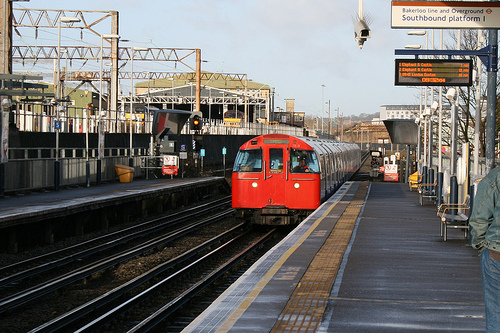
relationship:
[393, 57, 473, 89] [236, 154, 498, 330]
sign at a rail station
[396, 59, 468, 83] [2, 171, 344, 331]
sign at a railway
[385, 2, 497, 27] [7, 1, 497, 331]
sign at a train station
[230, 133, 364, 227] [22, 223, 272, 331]
red train on tracks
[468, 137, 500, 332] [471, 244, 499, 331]
man wears jeans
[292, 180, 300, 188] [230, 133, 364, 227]
headlight on red train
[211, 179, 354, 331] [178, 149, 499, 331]
line on platform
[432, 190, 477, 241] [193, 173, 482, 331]
bench on platform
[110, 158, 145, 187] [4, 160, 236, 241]
bucket on platform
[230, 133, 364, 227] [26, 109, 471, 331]
red train parked at station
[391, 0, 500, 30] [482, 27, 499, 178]
sign hangs from pole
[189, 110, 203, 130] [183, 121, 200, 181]
light on pole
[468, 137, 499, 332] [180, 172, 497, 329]
man on platform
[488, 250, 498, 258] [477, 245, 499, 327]
brown tag on jeans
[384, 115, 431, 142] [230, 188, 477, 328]
panel on platform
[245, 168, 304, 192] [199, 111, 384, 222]
light on train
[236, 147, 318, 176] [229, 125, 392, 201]
windshield on train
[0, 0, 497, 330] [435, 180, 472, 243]
station has seating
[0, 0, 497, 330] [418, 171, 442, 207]
station has seating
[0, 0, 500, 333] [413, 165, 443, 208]
station has seating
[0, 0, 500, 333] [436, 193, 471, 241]
station has bench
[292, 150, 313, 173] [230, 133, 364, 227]
person on red train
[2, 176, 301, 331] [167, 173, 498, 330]
railway line on ground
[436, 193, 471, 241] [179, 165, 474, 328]
bench on platform